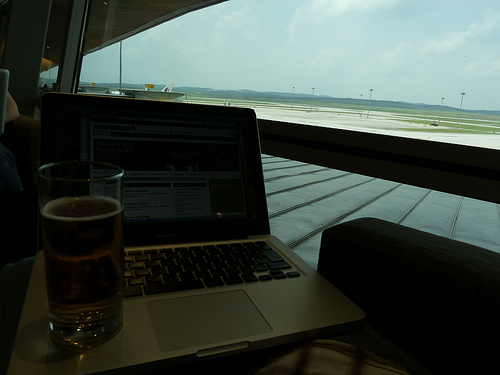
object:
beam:
[53, 0, 92, 94]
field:
[187, 93, 498, 150]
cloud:
[118, 0, 499, 108]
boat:
[117, 88, 187, 100]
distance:
[73, 55, 495, 117]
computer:
[5, 91, 368, 375]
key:
[190, 269, 214, 279]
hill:
[169, 84, 496, 113]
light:
[47, 305, 125, 365]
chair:
[0, 215, 500, 375]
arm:
[313, 215, 498, 356]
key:
[122, 240, 301, 298]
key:
[232, 250, 248, 260]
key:
[201, 276, 225, 288]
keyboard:
[50, 236, 302, 301]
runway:
[181, 96, 499, 150]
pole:
[455, 91, 467, 130]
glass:
[35, 157, 125, 351]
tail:
[161, 82, 176, 92]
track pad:
[146, 288, 275, 353]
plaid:
[285, 337, 383, 374]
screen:
[42, 92, 271, 248]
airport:
[36, 0, 500, 152]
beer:
[39, 194, 125, 352]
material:
[389, 324, 422, 352]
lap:
[256, 340, 409, 375]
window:
[68, 0, 500, 154]